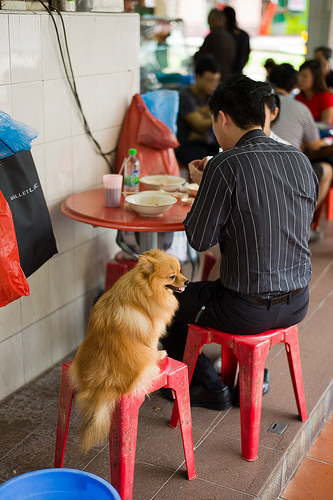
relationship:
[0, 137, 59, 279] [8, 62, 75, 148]
bag hanging on wall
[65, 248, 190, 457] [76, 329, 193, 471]
dog sitting on red chair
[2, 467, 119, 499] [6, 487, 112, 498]
container with water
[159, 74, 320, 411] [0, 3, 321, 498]
guy sitting in restaurant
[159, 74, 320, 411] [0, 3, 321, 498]
guy eating in restaurant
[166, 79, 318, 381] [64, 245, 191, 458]
couple eating with dog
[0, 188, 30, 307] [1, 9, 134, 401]
bag hanging on wall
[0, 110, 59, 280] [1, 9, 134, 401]
bag hanging on wall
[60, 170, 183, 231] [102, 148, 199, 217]
table food with table food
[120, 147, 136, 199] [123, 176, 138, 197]
bottle of water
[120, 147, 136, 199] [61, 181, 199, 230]
bottle on table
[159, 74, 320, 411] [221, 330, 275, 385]
guy sitting on stool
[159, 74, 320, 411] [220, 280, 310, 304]
guy wearing belt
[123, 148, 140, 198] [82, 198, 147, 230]
bottle on table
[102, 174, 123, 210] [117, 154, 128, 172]
cup with straw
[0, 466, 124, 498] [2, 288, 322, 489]
bucket on ground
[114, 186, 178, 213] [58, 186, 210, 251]
white bowls on table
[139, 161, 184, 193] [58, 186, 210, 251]
white bowls on table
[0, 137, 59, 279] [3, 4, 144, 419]
bag hanging on wall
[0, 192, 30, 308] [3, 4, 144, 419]
bag hanging on wall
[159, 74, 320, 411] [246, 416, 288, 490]
guy on edge of curb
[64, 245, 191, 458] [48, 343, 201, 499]
dog sitting on stool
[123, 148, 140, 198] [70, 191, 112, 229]
bottle on table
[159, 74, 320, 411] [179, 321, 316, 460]
guy sitting on red stool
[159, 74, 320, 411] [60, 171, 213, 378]
guy sitting at table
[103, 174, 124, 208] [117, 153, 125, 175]
cup with straw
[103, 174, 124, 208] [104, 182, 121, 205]
cup with drink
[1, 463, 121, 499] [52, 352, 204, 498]
blue object behind stool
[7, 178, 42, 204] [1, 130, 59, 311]
writing on bag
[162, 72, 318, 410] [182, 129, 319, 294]
guy wearing shirt